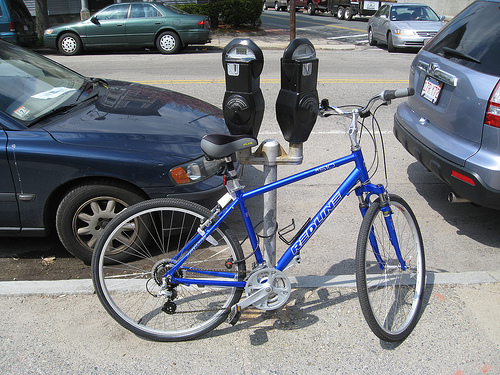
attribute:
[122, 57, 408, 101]
lines — white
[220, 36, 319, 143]
meters — parking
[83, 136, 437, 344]
bicycle — blue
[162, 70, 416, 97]
paint — yellow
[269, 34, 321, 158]
meter — parking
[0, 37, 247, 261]
car — blue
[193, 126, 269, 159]
seat — grey, black, bike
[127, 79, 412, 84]
lines — yellow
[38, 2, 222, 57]
car — parked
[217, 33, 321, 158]
meter — parking